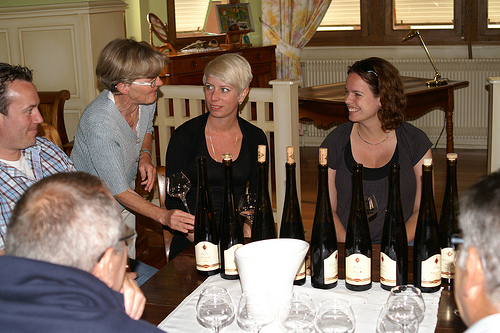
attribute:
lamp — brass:
[394, 30, 449, 85]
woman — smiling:
[313, 67, 433, 263]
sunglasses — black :
[339, 66, 387, 104]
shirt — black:
[166, 114, 273, 232]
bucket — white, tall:
[232, 232, 327, 331]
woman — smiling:
[308, 47, 458, 287]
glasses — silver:
[120, 74, 160, 87]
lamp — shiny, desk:
[397, 26, 444, 85]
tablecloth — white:
[157, 271, 444, 330]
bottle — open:
[340, 158, 375, 285]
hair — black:
[348, 59, 406, 135]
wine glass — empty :
[189, 278, 227, 330]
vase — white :
[235, 234, 307, 329]